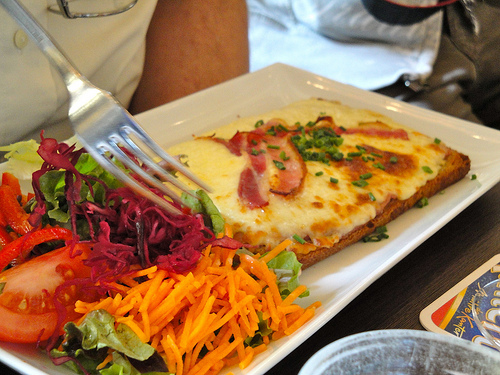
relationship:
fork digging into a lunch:
[2, 1, 214, 219] [3, 82, 476, 367]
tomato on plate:
[0, 225, 116, 349] [0, 55, 500, 373]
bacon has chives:
[218, 100, 306, 220] [250, 112, 365, 184]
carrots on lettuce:
[97, 231, 294, 371] [18, 139, 298, 373]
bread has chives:
[150, 95, 470, 272] [229, 92, 427, 220]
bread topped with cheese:
[161, 81, 471, 252] [140, 74, 450, 256]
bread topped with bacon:
[161, 81, 471, 252] [199, 107, 322, 207]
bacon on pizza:
[194, 115, 419, 211] [153, 82, 480, 259]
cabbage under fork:
[12, 120, 338, 370] [0, 0, 222, 232]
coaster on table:
[412, 246, 498, 360] [248, 123, 498, 368]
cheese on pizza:
[162, 93, 450, 248] [145, 93, 472, 271]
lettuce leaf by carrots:
[59, 310, 155, 363] [71, 241, 319, 372]